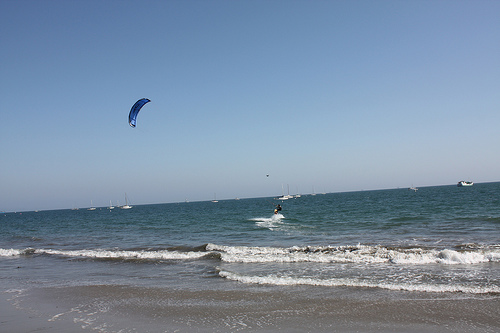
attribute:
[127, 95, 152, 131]
sail — blue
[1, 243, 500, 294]
waves — white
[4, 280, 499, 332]
shore — sandy, wet, brown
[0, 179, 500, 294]
ocean — water, blue, calm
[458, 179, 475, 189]
boat — white, on the horizon, without mast, in the distance, in distance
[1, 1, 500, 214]
air — blue, clear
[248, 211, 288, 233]
wave — small